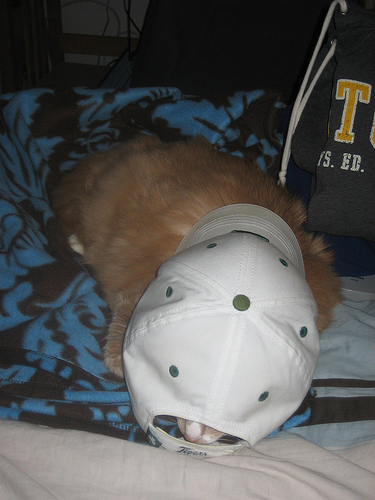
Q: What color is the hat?
A: White.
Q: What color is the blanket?
A: Blue.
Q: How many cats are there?
A: One.